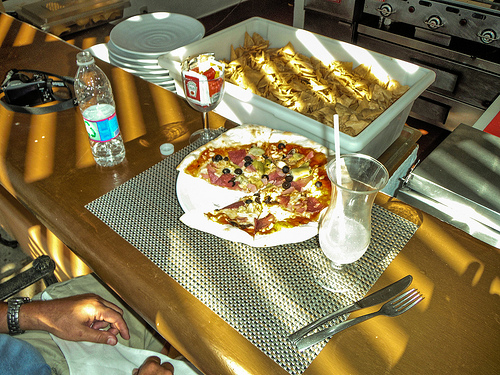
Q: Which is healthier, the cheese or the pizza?
A: The cheese is healthier than the pizza.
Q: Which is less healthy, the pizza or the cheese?
A: The pizza is less healthy than the cheese.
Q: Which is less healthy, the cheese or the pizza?
A: The pizza is less healthy than the cheese.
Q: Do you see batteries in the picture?
A: No, there are no batteries.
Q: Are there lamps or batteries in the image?
A: No, there are no batteries or lamps.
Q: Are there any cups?
A: Yes, there is a cup.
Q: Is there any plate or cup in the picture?
A: Yes, there is a cup.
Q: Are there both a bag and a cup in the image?
A: No, there is a cup but no bags.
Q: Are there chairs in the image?
A: No, there are no chairs.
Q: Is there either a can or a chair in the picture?
A: No, there are no chairs or cans.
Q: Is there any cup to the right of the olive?
A: Yes, there is a cup to the right of the olive.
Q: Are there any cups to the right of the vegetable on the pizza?
A: Yes, there is a cup to the right of the olive.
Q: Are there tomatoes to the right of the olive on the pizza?
A: No, there is a cup to the right of the olive.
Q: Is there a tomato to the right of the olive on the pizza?
A: No, there is a cup to the right of the olive.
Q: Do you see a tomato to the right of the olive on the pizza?
A: No, there is a cup to the right of the olive.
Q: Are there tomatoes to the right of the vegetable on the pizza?
A: No, there is a cup to the right of the olive.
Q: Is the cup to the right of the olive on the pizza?
A: Yes, the cup is to the right of the olive.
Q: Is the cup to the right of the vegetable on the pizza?
A: Yes, the cup is to the right of the olive.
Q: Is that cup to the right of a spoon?
A: No, the cup is to the right of the olive.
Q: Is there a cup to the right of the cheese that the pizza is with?
A: Yes, there is a cup to the right of the cheese.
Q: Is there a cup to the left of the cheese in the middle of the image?
A: No, the cup is to the right of the cheese.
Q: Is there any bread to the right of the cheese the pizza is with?
A: No, there is a cup to the right of the cheese.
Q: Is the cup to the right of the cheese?
A: Yes, the cup is to the right of the cheese.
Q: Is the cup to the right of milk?
A: No, the cup is to the right of the cheese.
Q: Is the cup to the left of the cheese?
A: No, the cup is to the right of the cheese.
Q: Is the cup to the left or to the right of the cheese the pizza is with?
A: The cup is to the right of the cheese.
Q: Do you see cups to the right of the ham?
A: Yes, there is a cup to the right of the ham.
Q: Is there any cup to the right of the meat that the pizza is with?
A: Yes, there is a cup to the right of the ham.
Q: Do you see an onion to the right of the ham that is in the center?
A: No, there is a cup to the right of the ham.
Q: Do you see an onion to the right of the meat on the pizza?
A: No, there is a cup to the right of the ham.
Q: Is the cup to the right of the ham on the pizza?
A: Yes, the cup is to the right of the ham.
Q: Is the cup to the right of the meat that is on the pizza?
A: Yes, the cup is to the right of the ham.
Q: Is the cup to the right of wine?
A: No, the cup is to the right of the ham.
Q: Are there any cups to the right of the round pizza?
A: Yes, there is a cup to the right of the pizza.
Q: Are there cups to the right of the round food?
A: Yes, there is a cup to the right of the pizza.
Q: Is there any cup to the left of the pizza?
A: No, the cup is to the right of the pizza.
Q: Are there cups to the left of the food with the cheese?
A: No, the cup is to the right of the pizza.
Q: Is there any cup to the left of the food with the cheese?
A: No, the cup is to the right of the pizza.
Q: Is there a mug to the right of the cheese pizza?
A: No, there is a cup to the right of the pizza.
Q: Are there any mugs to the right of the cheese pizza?
A: No, there is a cup to the right of the pizza.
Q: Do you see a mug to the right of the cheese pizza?
A: No, there is a cup to the right of the pizza.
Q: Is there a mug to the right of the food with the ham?
A: No, there is a cup to the right of the pizza.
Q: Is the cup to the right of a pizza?
A: Yes, the cup is to the right of a pizza.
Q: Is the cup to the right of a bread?
A: No, the cup is to the right of a pizza.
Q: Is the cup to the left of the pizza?
A: No, the cup is to the right of the pizza.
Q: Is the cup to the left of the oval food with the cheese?
A: No, the cup is to the right of the pizza.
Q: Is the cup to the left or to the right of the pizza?
A: The cup is to the right of the pizza.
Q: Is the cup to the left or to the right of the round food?
A: The cup is to the right of the pizza.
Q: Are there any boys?
A: No, there are no boys.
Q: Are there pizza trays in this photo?
A: No, there are no pizza trays.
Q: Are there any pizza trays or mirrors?
A: No, there are no pizza trays or mirrors.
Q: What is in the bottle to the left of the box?
A: The water is in the bottle.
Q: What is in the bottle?
A: The water is in the bottle.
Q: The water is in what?
A: The water is in the bottle.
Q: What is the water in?
A: The water is in the bottle.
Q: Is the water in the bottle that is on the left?
A: Yes, the water is in the bottle.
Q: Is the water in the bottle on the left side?
A: Yes, the water is in the bottle.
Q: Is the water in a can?
A: No, the water is in the bottle.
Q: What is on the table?
A: The water is on the table.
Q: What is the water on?
A: The water is on the table.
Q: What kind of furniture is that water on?
A: The water is on the table.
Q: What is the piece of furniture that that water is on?
A: The piece of furniture is a table.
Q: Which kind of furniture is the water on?
A: The water is on the table.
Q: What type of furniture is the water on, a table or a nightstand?
A: The water is on a table.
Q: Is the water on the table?
A: Yes, the water is on the table.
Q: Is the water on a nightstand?
A: No, the water is on the table.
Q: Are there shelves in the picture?
A: No, there are no shelves.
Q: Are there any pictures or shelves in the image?
A: No, there are no shelves or pictures.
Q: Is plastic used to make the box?
A: Yes, the box is made of plastic.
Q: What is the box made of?
A: The box is made of plastic.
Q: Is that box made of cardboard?
A: No, the box is made of plastic.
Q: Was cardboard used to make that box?
A: No, the box is made of plastic.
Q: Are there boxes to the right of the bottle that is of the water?
A: Yes, there is a box to the right of the bottle.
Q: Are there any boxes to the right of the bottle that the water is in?
A: Yes, there is a box to the right of the bottle.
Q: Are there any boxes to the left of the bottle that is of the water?
A: No, the box is to the right of the bottle.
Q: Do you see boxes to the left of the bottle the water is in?
A: No, the box is to the right of the bottle.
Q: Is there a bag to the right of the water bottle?
A: No, there is a box to the right of the bottle.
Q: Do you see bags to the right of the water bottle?
A: No, there is a box to the right of the bottle.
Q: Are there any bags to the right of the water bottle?
A: No, there is a box to the right of the bottle.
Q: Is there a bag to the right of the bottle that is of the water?
A: No, there is a box to the right of the bottle.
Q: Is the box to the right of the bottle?
A: Yes, the box is to the right of the bottle.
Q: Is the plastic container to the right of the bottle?
A: Yes, the box is to the right of the bottle.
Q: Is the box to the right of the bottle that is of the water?
A: Yes, the box is to the right of the bottle.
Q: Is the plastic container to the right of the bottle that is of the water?
A: Yes, the box is to the right of the bottle.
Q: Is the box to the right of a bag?
A: No, the box is to the right of the bottle.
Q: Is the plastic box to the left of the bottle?
A: No, the box is to the right of the bottle.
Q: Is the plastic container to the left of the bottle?
A: No, the box is to the right of the bottle.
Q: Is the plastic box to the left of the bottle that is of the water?
A: No, the box is to the right of the bottle.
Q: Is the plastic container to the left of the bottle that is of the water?
A: No, the box is to the right of the bottle.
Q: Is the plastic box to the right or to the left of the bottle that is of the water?
A: The box is to the right of the bottle.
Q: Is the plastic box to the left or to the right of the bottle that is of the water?
A: The box is to the right of the bottle.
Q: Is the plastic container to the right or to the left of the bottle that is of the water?
A: The box is to the right of the bottle.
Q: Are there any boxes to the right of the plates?
A: Yes, there is a box to the right of the plates.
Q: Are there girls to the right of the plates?
A: No, there is a box to the right of the plates.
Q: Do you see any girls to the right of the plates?
A: No, there is a box to the right of the plates.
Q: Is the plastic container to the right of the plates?
A: Yes, the box is to the right of the plates.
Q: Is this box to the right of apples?
A: No, the box is to the right of the plates.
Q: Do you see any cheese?
A: Yes, there is cheese.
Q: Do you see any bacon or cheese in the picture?
A: Yes, there is cheese.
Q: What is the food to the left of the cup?
A: The food is cheese.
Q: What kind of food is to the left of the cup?
A: The food is cheese.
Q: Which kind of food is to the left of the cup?
A: The food is cheese.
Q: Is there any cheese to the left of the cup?
A: Yes, there is cheese to the left of the cup.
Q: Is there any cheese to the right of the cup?
A: No, the cheese is to the left of the cup.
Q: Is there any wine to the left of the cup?
A: No, there is cheese to the left of the cup.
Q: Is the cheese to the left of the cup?
A: Yes, the cheese is to the left of the cup.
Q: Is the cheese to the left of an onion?
A: No, the cheese is to the left of the cup.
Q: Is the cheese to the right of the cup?
A: No, the cheese is to the left of the cup.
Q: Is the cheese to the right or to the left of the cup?
A: The cheese is to the left of the cup.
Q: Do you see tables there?
A: Yes, there is a table.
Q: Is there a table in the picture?
A: Yes, there is a table.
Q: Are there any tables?
A: Yes, there is a table.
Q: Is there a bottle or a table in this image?
A: Yes, there is a table.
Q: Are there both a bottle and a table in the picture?
A: Yes, there are both a table and a bottle.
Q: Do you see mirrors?
A: No, there are no mirrors.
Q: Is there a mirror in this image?
A: No, there are no mirrors.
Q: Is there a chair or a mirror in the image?
A: No, there are no mirrors or chairs.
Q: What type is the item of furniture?
A: The piece of furniture is a table.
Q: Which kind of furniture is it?
A: The piece of furniture is a table.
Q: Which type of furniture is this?
A: This is a table.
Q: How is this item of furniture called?
A: This is a table.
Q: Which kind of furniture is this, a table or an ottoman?
A: This is a table.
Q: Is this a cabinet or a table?
A: This is a table.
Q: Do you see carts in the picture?
A: No, there are no carts.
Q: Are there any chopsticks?
A: No, there are no chopsticks.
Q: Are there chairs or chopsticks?
A: No, there are no chopsticks or chairs.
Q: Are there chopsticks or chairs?
A: No, there are no chopsticks or chairs.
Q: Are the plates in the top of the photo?
A: Yes, the plates are in the top of the image.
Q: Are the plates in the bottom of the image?
A: No, the plates are in the top of the image.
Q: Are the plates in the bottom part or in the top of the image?
A: The plates are in the top of the image.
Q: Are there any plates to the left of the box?
A: Yes, there are plates to the left of the box.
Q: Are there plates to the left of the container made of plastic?
A: Yes, there are plates to the left of the box.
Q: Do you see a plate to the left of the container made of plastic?
A: Yes, there are plates to the left of the box.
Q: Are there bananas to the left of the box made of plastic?
A: No, there are plates to the left of the box.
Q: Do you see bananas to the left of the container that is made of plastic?
A: No, there are plates to the left of the box.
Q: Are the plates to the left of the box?
A: Yes, the plates are to the left of the box.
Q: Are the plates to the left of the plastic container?
A: Yes, the plates are to the left of the box.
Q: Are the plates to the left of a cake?
A: No, the plates are to the left of the box.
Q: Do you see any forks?
A: Yes, there is a fork.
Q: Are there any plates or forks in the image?
A: Yes, there is a fork.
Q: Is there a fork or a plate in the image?
A: Yes, there is a fork.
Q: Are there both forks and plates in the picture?
A: Yes, there are both a fork and a plate.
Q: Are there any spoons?
A: No, there are no spoons.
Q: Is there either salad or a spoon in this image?
A: No, there are no spoons or salad.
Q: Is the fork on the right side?
A: Yes, the fork is on the right of the image.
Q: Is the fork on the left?
A: No, the fork is on the right of the image.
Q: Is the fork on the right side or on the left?
A: The fork is on the right of the image.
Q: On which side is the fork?
A: The fork is on the right of the image.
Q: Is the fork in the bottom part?
A: Yes, the fork is in the bottom of the image.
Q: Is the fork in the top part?
A: No, the fork is in the bottom of the image.